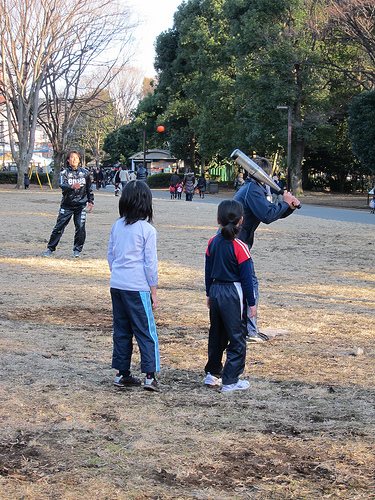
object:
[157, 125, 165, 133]
ball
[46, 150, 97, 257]
man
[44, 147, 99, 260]
outfit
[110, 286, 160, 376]
pant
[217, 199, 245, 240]
hair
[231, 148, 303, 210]
bat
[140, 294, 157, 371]
stripe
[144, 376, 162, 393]
sneakers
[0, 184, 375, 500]
dirt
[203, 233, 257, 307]
shirt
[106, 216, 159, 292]
shirt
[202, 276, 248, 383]
pants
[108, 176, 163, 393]
child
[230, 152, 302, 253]
people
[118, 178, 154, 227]
hair